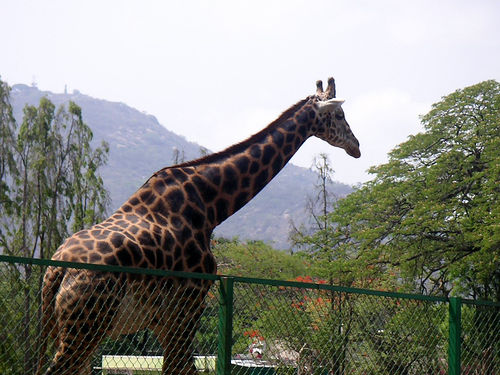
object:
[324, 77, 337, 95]
horns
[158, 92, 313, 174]
hair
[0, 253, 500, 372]
fence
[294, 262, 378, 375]
tree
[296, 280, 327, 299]
flowers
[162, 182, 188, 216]
spot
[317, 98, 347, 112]
ear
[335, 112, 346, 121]
eye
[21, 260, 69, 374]
tail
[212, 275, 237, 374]
post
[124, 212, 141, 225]
spots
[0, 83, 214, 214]
mountain range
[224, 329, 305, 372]
building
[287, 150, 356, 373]
tree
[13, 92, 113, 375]
tree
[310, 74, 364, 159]
head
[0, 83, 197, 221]
hillside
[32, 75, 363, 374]
zebra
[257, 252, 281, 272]
leaves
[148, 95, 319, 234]
neck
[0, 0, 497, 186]
sky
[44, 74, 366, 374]
animal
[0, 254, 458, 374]
gate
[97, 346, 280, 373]
building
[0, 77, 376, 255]
hills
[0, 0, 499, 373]
outside